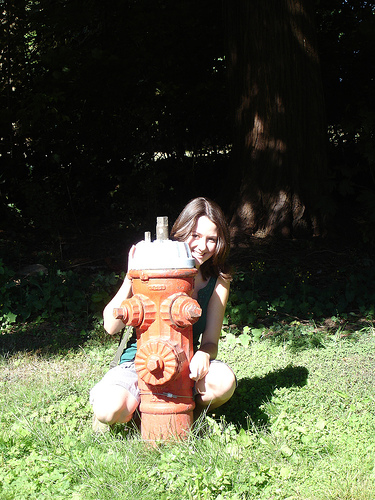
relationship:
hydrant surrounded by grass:
[110, 215, 203, 446] [2, 281, 371, 499]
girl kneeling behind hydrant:
[88, 193, 240, 435] [110, 215, 203, 446]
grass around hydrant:
[2, 281, 371, 499] [110, 215, 203, 446]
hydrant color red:
[110, 215, 203, 446] [113, 270, 200, 453]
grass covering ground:
[2, 281, 371, 499] [4, 233, 374, 498]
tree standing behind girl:
[76, 2, 342, 253] [90, 198, 236, 435]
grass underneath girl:
[2, 281, 371, 499] [90, 198, 236, 435]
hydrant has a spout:
[110, 215, 203, 446] [164, 292, 205, 327]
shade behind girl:
[5, 167, 375, 359] [90, 198, 236, 435]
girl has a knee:
[88, 193, 240, 435] [88, 383, 131, 425]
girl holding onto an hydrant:
[90, 198, 236, 435] [114, 215, 202, 441]